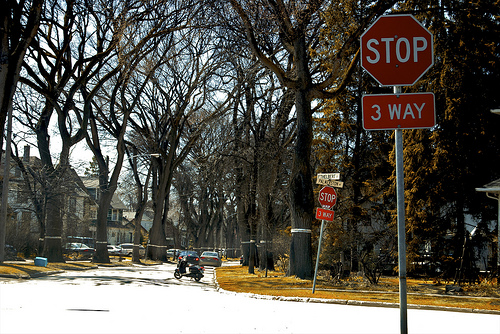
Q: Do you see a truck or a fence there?
A: No, there are no fences or trucks.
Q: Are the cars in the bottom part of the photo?
A: Yes, the cars are in the bottom of the image.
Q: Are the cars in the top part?
A: No, the cars are in the bottom of the image.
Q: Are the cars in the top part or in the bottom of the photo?
A: The cars are in the bottom of the image.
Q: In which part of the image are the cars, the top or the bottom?
A: The cars are in the bottom of the image.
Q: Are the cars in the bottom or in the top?
A: The cars are in the bottom of the image.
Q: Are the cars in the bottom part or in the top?
A: The cars are in the bottom of the image.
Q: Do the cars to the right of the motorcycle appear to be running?
A: Yes, the cars are running.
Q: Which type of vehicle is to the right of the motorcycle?
A: The vehicles are cars.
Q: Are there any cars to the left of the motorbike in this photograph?
A: No, the cars are to the right of the motorbike.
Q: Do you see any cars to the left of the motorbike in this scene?
A: No, the cars are to the right of the motorbike.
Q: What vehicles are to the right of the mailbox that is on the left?
A: The vehicles are cars.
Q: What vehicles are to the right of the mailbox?
A: The vehicles are cars.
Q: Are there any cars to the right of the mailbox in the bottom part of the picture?
A: Yes, there are cars to the right of the mailbox.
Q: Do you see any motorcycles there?
A: Yes, there is a motorcycle.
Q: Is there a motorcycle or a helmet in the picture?
A: Yes, there is a motorcycle.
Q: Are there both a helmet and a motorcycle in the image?
A: No, there is a motorcycle but no helmets.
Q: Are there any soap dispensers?
A: No, there are no soap dispensers.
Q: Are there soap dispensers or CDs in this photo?
A: No, there are no soap dispensers or cds.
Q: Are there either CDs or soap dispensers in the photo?
A: No, there are no soap dispensers or cds.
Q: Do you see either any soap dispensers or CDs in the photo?
A: No, there are no soap dispensers or cds.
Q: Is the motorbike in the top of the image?
A: No, the motorbike is in the bottom of the image.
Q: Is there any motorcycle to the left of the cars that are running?
A: Yes, there is a motorcycle to the left of the cars.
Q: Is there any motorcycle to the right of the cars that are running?
A: No, the motorcycle is to the left of the cars.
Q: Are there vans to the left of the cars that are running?
A: No, there is a motorcycle to the left of the cars.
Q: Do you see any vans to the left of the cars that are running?
A: No, there is a motorcycle to the left of the cars.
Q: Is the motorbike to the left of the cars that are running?
A: Yes, the motorbike is to the left of the cars.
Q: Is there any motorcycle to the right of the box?
A: Yes, there is a motorcycle to the right of the box.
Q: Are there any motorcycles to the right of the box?
A: Yes, there is a motorcycle to the right of the box.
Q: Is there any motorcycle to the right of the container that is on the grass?
A: Yes, there is a motorcycle to the right of the box.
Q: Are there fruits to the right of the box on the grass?
A: No, there is a motorcycle to the right of the box.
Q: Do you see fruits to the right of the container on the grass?
A: No, there is a motorcycle to the right of the box.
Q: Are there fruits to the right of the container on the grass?
A: No, there is a motorcycle to the right of the box.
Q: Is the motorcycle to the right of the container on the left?
A: Yes, the motorcycle is to the right of the box.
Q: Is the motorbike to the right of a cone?
A: No, the motorbike is to the right of the box.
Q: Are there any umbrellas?
A: No, there are no umbrellas.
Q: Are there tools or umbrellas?
A: No, there are no umbrellas or tools.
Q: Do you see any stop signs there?
A: Yes, there is a stop sign.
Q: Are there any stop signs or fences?
A: Yes, there is a stop sign.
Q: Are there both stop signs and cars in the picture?
A: Yes, there are both a stop sign and a car.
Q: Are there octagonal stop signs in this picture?
A: Yes, there is an octagonal stop sign.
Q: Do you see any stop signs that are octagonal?
A: Yes, there is a stop sign that is octagonal.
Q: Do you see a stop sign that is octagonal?
A: Yes, there is a stop sign that is octagonal.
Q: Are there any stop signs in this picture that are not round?
A: Yes, there is a octagonal stop sign.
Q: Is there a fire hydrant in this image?
A: No, there are no fire hydrants.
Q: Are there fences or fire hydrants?
A: No, there are no fire hydrants or fences.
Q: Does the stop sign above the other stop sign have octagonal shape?
A: Yes, the stop sign is octagonal.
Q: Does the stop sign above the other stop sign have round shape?
A: No, the stop sign is octagonal.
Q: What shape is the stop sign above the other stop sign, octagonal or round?
A: The stop sign is octagonal.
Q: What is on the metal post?
A: The stop sign is on the post.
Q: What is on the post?
A: The stop sign is on the post.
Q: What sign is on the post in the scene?
A: The sign is a stop sign.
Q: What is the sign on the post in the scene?
A: The sign is a stop sign.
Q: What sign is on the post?
A: The sign is a stop sign.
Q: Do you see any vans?
A: No, there are no vans.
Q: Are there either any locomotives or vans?
A: No, there are no vans or locomotives.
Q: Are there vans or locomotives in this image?
A: No, there are no vans or locomotives.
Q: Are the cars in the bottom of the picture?
A: Yes, the cars are in the bottom of the image.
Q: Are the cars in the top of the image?
A: No, the cars are in the bottom of the image.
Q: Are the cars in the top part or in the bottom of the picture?
A: The cars are in the bottom of the image.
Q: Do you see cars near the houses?
A: Yes, there are cars near the houses.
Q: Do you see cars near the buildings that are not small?
A: Yes, there are cars near the houses.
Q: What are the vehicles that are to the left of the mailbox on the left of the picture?
A: The vehicles are cars.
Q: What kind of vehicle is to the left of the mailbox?
A: The vehicles are cars.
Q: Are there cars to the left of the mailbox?
A: Yes, there are cars to the left of the mailbox.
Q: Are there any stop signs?
A: Yes, there is a stop sign.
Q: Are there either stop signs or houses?
A: Yes, there is a stop sign.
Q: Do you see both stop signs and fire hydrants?
A: No, there is a stop sign but no fire hydrants.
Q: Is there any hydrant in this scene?
A: No, there are no fire hydrants.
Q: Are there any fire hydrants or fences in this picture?
A: No, there are no fire hydrants or fences.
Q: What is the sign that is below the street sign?
A: The sign is a stop sign.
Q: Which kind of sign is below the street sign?
A: The sign is a stop sign.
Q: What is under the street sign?
A: The stop sign is under the street sign.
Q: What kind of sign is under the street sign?
A: The sign is a stop sign.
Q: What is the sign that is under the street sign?
A: The sign is a stop sign.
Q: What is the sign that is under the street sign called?
A: The sign is a stop sign.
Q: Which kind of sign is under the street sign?
A: The sign is a stop sign.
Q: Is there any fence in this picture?
A: No, there are no fences.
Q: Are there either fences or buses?
A: No, there are no fences or buses.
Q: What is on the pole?
A: The sign is on the pole.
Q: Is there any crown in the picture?
A: No, there are no crowns.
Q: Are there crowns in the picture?
A: No, there are no crowns.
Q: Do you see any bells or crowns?
A: No, there are no crowns or bells.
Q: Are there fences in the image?
A: No, there are no fences.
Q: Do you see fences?
A: No, there are no fences.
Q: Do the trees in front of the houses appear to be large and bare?
A: Yes, the trees are large and bare.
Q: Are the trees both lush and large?
A: No, the trees are large but bare.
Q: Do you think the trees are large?
A: Yes, the trees are large.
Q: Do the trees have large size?
A: Yes, the trees are large.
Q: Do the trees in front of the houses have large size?
A: Yes, the trees are large.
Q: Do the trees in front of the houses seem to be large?
A: Yes, the trees are large.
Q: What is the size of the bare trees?
A: The trees are large.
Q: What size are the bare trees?
A: The trees are large.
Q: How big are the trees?
A: The trees are large.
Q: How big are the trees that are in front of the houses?
A: The trees are large.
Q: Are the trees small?
A: No, the trees are large.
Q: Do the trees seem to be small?
A: No, the trees are large.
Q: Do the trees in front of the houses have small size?
A: No, the trees are large.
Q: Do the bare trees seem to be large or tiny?
A: The trees are large.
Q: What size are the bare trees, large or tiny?
A: The trees are large.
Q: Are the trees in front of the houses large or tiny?
A: The trees are large.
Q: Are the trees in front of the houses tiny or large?
A: The trees are large.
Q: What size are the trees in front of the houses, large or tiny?
A: The trees are large.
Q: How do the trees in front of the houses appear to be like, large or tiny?
A: The trees are large.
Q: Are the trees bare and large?
A: Yes, the trees are bare and large.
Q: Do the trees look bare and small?
A: No, the trees are bare but large.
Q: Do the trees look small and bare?
A: No, the trees are bare but large.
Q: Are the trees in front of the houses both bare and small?
A: No, the trees are bare but large.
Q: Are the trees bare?
A: Yes, the trees are bare.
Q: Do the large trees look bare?
A: Yes, the trees are bare.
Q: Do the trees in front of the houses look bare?
A: Yes, the trees are bare.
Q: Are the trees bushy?
A: No, the trees are bare.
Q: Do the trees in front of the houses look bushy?
A: No, the trees are bare.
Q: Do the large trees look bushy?
A: No, the trees are bare.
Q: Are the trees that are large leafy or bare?
A: The trees are bare.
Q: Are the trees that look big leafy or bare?
A: The trees are bare.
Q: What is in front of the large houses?
A: The trees are in front of the houses.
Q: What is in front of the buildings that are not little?
A: The trees are in front of the houses.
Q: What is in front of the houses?
A: The trees are in front of the houses.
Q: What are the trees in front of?
A: The trees are in front of the houses.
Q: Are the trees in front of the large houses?
A: Yes, the trees are in front of the houses.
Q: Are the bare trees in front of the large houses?
A: Yes, the trees are in front of the houses.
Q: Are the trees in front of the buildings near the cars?
A: Yes, the trees are in front of the houses.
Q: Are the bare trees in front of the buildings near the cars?
A: Yes, the trees are in front of the houses.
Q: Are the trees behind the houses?
A: No, the trees are in front of the houses.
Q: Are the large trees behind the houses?
A: No, the trees are in front of the houses.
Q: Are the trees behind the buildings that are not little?
A: No, the trees are in front of the houses.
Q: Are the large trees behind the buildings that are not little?
A: No, the trees are in front of the houses.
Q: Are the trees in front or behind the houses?
A: The trees are in front of the houses.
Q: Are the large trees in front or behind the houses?
A: The trees are in front of the houses.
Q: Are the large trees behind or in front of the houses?
A: The trees are in front of the houses.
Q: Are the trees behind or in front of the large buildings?
A: The trees are in front of the houses.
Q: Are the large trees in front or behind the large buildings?
A: The trees are in front of the houses.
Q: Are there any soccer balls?
A: No, there are no soccer balls.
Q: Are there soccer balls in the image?
A: No, there are no soccer balls.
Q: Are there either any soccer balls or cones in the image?
A: No, there are no soccer balls or cones.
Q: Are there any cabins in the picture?
A: No, there are no cabins.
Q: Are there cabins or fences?
A: No, there are no cabins or fences.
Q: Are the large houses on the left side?
A: Yes, the houses are on the left of the image.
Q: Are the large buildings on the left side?
A: Yes, the houses are on the left of the image.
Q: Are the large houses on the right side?
A: No, the houses are on the left of the image.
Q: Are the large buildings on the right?
A: No, the houses are on the left of the image.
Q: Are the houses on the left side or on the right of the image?
A: The houses are on the left of the image.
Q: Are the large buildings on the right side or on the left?
A: The houses are on the left of the image.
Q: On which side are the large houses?
A: The houses are on the left of the image.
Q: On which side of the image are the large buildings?
A: The houses are on the left of the image.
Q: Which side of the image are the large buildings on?
A: The houses are on the left of the image.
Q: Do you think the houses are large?
A: Yes, the houses are large.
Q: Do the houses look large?
A: Yes, the houses are large.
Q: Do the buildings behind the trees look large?
A: Yes, the houses are large.